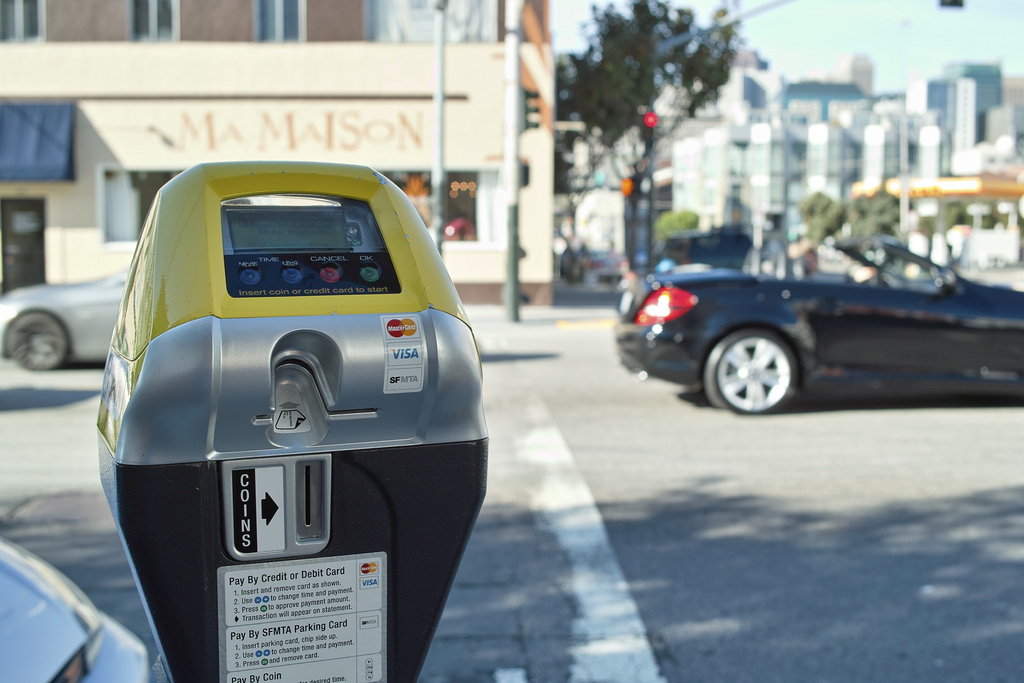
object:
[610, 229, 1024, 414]
vehicle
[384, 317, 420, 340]
logo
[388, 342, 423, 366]
logo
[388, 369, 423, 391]
logo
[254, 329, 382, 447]
card slot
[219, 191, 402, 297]
display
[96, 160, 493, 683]
parking meter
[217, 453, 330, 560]
coin slot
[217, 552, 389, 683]
directions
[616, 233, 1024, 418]
sportscar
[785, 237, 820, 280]
white man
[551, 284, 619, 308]
street corner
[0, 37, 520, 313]
boutique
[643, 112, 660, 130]
traffic light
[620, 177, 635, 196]
pedestrian light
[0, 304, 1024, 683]
street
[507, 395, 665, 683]
white stripe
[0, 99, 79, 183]
awning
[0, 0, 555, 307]
building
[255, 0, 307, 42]
window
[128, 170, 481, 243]
window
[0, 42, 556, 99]
wall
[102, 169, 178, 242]
window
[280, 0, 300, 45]
window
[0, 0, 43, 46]
window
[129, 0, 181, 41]
window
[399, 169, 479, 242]
window